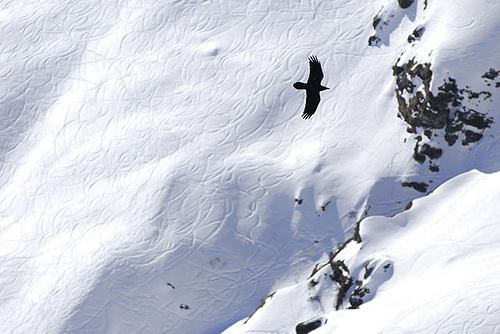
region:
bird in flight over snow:
[288, 50, 338, 125]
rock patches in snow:
[392, 56, 464, 151]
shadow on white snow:
[178, 226, 285, 298]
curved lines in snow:
[211, 94, 268, 149]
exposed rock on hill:
[309, 253, 359, 308]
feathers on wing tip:
[301, 52, 328, 70]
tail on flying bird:
[288, 79, 312, 94]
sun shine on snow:
[39, 169, 131, 280]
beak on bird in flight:
[322, 82, 337, 95]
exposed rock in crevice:
[391, 173, 436, 198]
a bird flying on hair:
[268, 40, 335, 122]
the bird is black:
[283, 55, 351, 130]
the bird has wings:
[276, 56, 370, 136]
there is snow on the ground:
[2, 2, 494, 327]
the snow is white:
[66, 40, 182, 176]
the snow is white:
[206, 166, 493, 332]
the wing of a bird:
[298, 50, 326, 80]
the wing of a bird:
[298, 90, 322, 120]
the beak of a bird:
[321, 83, 331, 95]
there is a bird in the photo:
[3, 0, 498, 331]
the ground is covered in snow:
[17, 27, 237, 262]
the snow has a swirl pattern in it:
[52, 69, 217, 244]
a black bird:
[277, 47, 341, 154]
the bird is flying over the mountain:
[279, 51, 337, 128]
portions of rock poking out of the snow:
[379, 39, 490, 153]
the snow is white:
[39, 67, 235, 244]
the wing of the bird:
[303, 52, 335, 83]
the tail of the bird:
[289, 79, 312, 96]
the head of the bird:
[320, 78, 332, 102]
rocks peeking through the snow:
[319, 221, 424, 312]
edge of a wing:
[286, 99, 315, 122]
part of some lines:
[240, 231, 268, 276]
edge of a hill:
[401, 94, 439, 171]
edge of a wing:
[286, 79, 317, 134]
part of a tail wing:
[286, 72, 303, 101]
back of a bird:
[291, 66, 324, 95]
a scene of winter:
[5, 6, 496, 323]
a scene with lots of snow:
[22, 7, 463, 332]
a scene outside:
[14, 3, 473, 331]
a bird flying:
[270, 48, 352, 138]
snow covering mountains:
[11, 5, 496, 330]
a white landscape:
[7, 5, 460, 332]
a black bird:
[278, 37, 343, 145]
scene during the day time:
[10, 8, 497, 330]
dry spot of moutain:
[376, 44, 493, 209]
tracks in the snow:
[9, 6, 284, 235]